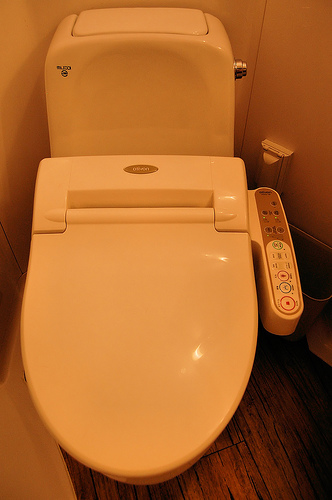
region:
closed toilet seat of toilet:
[13, 147, 308, 483]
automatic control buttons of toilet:
[253, 181, 308, 341]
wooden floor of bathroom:
[50, 321, 330, 496]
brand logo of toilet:
[123, 162, 160, 177]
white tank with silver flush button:
[39, 3, 250, 156]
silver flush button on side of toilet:
[233, 58, 250, 77]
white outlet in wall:
[252, 136, 297, 190]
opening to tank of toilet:
[70, 7, 211, 40]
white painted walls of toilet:
[7, 6, 330, 494]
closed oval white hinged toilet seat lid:
[18, 185, 259, 471]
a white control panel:
[254, 183, 304, 333]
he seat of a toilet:
[17, 153, 252, 482]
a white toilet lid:
[21, 158, 248, 480]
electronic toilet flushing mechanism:
[224, 56, 251, 79]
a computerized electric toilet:
[20, 151, 302, 484]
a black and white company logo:
[53, 60, 73, 78]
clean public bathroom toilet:
[17, 6, 308, 488]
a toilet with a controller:
[24, 7, 301, 488]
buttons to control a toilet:
[258, 188, 303, 340]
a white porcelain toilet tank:
[40, 8, 238, 153]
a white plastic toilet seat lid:
[18, 153, 258, 481]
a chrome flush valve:
[232, 58, 246, 80]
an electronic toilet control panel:
[250, 182, 301, 336]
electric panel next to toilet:
[251, 185, 302, 323]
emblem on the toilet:
[125, 161, 162, 178]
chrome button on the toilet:
[229, 56, 249, 79]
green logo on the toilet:
[54, 59, 72, 78]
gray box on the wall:
[251, 135, 294, 197]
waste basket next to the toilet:
[287, 224, 331, 320]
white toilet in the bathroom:
[25, 151, 251, 444]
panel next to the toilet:
[253, 187, 302, 324]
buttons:
[266, 254, 301, 319]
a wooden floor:
[253, 442, 281, 469]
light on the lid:
[183, 342, 212, 363]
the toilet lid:
[99, 377, 154, 436]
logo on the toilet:
[122, 161, 161, 175]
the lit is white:
[41, 283, 127, 387]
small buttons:
[263, 193, 290, 248]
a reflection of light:
[189, 336, 214, 363]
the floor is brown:
[228, 458, 264, 490]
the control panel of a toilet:
[242, 180, 304, 348]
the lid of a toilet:
[31, 242, 250, 462]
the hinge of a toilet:
[48, 195, 209, 233]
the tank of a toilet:
[38, 22, 243, 160]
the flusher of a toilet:
[219, 42, 261, 90]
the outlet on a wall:
[246, 135, 291, 192]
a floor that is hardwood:
[246, 383, 310, 492]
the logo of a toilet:
[38, 59, 79, 91]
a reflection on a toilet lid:
[183, 331, 227, 379]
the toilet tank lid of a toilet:
[70, 2, 204, 48]